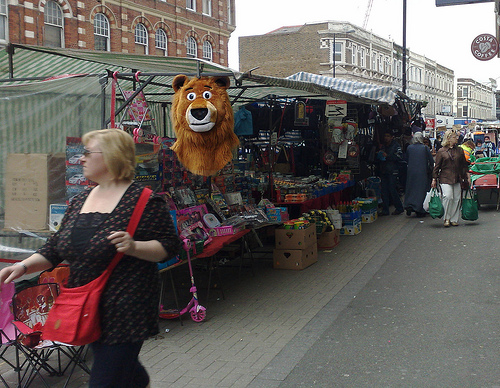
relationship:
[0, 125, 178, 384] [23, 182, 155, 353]
woman has bag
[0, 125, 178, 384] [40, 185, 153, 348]
woman has purse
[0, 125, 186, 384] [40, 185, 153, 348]
woman has purse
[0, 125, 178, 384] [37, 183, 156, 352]
woman has bag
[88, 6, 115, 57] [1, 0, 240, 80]
window on building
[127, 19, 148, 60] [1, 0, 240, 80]
window on building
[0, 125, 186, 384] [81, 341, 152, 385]
woman wearing pants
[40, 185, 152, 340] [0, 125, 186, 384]
purse being carried by woman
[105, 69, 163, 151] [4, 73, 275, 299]
stroller hanging from tent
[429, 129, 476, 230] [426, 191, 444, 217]
woman carrying bag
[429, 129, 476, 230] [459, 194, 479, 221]
woman carrying bag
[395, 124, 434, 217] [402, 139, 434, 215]
woman wearing coat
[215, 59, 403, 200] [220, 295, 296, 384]
tent on a sidewalk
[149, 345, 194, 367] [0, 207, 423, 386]
bricks are on a sidewalk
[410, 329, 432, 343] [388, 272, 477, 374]
asphalt on ground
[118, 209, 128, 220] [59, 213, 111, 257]
pattern on shirt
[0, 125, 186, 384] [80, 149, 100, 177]
woman has a face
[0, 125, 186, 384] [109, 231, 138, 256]
woman has a hand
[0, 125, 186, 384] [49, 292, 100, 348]
woman wearing a purse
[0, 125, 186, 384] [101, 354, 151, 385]
woman wearing a pants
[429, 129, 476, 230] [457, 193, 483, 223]
woman holding bag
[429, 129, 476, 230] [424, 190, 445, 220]
woman holding bag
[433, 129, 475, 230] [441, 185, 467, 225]
woman wearing pants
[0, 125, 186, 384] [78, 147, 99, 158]
woman wearing glasses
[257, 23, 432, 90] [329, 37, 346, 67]
building has a window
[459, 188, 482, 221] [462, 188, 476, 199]
bag has handles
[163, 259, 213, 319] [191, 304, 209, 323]
scooter has a wheel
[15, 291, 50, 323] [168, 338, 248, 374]
folding chair on ground